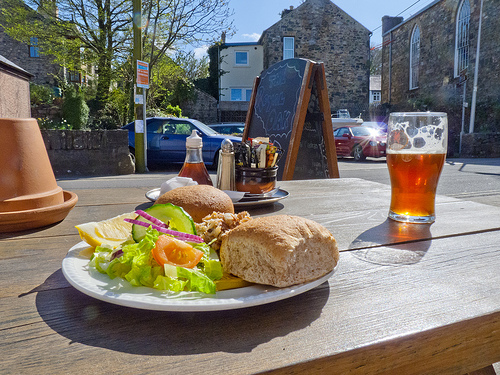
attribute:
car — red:
[330, 121, 393, 162]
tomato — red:
[149, 229, 210, 271]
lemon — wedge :
[71, 207, 143, 247]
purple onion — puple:
[123, 206, 202, 242]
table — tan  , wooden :
[0, 177, 498, 371]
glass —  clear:
[367, 100, 465, 254]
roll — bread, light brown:
[225, 212, 353, 299]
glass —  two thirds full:
[375, 94, 457, 236]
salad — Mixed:
[117, 206, 222, 295]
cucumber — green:
[126, 203, 195, 247]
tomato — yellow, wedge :
[147, 230, 205, 280]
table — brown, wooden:
[65, 140, 482, 369]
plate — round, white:
[61, 243, 334, 316]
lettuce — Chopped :
[81, 220, 221, 298]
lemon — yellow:
[74, 195, 161, 251]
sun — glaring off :
[342, 100, 407, 160]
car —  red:
[328, 114, 387, 162]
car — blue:
[96, 113, 266, 173]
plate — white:
[66, 208, 337, 314]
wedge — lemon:
[64, 199, 153, 254]